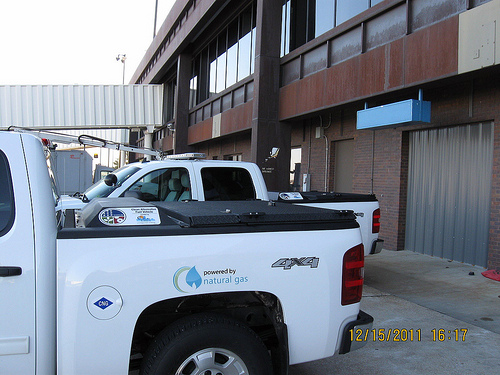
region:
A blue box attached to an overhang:
[348, 103, 445, 125]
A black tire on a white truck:
[139, 311, 274, 374]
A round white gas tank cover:
[85, 278, 127, 326]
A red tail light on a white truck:
[341, 239, 363, 309]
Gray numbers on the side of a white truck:
[272, 254, 322, 271]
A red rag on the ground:
[475, 263, 498, 288]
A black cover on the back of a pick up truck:
[152, 203, 352, 224]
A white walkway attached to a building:
[2, 83, 169, 130]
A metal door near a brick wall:
[402, 123, 497, 275]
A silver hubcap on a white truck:
[172, 345, 249, 374]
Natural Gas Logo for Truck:
[158, 253, 258, 307]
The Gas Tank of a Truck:
[60, 277, 131, 333]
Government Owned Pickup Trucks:
[9, 105, 329, 368]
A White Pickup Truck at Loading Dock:
[144, 84, 480, 290]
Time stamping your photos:
[226, 177, 498, 366]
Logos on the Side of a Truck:
[56, 162, 333, 349]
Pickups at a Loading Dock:
[0, 97, 455, 374]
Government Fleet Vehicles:
[60, 120, 405, 317]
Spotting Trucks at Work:
[51, 109, 498, 368]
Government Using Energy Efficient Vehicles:
[17, 102, 489, 372]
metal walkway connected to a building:
[0, 75, 178, 156]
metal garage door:
[396, 129, 498, 259]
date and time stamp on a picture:
[336, 314, 476, 354]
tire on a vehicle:
[123, 293, 289, 373]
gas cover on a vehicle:
[69, 265, 130, 329]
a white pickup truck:
[3, 131, 366, 357]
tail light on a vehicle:
[339, 237, 372, 313]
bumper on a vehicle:
[318, 298, 380, 356]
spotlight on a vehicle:
[83, 158, 138, 190]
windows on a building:
[178, 34, 263, 96]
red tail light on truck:
[333, 251, 377, 306]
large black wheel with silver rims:
[148, 328, 284, 373]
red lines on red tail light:
[344, 261, 371, 290]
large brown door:
[318, 129, 375, 191]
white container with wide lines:
[2, 79, 180, 130]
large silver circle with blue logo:
[84, 279, 126, 339]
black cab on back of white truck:
[67, 186, 367, 261]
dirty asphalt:
[389, 280, 499, 317]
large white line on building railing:
[190, 99, 247, 142]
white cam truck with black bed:
[88, 156, 412, 240]